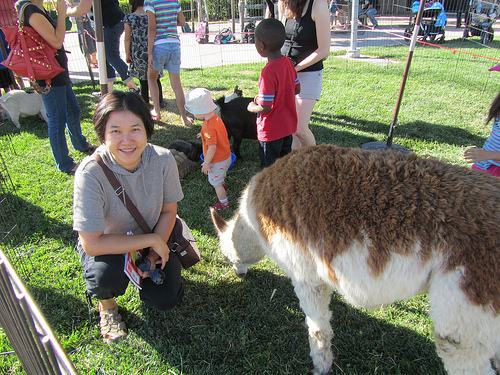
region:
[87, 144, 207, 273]
Brown bag woman is carrying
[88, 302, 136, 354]
White shoes woman is wearing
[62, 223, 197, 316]
Dark pants woman is wearing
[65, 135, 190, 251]
Gray shirt woman is wearing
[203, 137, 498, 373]
Brown and white animal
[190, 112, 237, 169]
Orange shirt child is wearing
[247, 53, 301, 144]
Red shirt child is wearing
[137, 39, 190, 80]
Jean shorts person is wearing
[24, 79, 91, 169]
Jean pants person is wearing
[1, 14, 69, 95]
Red bag person is carrying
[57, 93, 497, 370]
woman posing with llama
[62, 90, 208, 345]
woman wearing gray shirt kneeling down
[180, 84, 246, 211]
little boy wearing orange shirt and khaki hat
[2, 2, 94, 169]
woman carrying red purse with gold studs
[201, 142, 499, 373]
white and brown llama grazing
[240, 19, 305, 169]
young boy wearing red shirt and black pants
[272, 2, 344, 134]
woman wearing black tanktop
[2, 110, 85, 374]
fencing on the left side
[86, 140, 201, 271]
brown bag of woman wearing grey shirt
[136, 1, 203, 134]
person wearing striped shirt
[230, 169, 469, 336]
brown and white sheep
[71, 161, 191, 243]
gray sweatshirt on woman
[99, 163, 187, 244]
brown leather strap on woman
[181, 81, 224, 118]
white bucket hat on child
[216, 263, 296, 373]
shadow of animal and woman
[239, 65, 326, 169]
red shirt and blue stripe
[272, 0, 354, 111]
woman with black tank and shorts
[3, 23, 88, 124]
red leather bag with gold gems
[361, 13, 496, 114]
wired fence gate for zoo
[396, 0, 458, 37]
blue and black stroller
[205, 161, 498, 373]
an animal eating grass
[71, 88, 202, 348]
a woman kneeling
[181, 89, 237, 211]
a young boy playing with animals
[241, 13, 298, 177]
a young boy watching animals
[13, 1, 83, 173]
a woman talking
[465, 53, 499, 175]
A young girl watching animals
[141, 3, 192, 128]
a young woman watching animals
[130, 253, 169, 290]
black sunglasses in the womans hand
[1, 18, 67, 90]
red purse on the womans shoulder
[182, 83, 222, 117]
white hat on the boy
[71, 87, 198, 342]
woman is kneeling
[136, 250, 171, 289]
person has sunglasses in hand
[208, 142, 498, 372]
animal is white and brown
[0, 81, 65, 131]
small white animal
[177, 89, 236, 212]
person has on white hat orange shirt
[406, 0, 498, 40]
strollers in the background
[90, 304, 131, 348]
person has on athletic shoe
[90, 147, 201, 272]
person has brown and pink purse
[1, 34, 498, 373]
grass is short and green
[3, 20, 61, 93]
large red purse